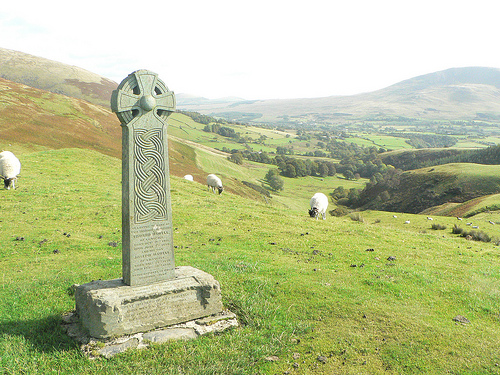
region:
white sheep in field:
[300, 197, 335, 231]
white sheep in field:
[205, 169, 230, 203]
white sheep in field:
[180, 166, 200, 187]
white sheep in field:
[0, 146, 27, 203]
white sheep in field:
[403, 216, 415, 231]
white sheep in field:
[389, 206, 396, 218]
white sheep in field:
[423, 214, 435, 222]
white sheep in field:
[457, 214, 465, 221]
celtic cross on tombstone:
[65, 63, 240, 354]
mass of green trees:
[283, 155, 346, 174]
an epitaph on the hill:
[86, 51, 243, 330]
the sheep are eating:
[209, 157, 353, 247]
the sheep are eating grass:
[207, 163, 364, 250]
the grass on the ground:
[205, 180, 357, 316]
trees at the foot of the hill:
[235, 134, 387, 227]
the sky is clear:
[180, 23, 344, 100]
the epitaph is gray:
[84, 57, 209, 274]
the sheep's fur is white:
[3, 144, 56, 226]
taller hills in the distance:
[285, 46, 497, 158]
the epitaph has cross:
[68, 82, 273, 334]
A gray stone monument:
[43, 65, 249, 361]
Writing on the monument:
[40, 62, 246, 359]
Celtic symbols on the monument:
[50, 50, 251, 365]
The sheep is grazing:
[301, 190, 332, 220]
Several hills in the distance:
[215, 55, 497, 185]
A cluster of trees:
[268, 151, 388, 182]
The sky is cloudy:
[8, 5, 498, 64]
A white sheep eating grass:
[202, 167, 228, 201]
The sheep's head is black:
[2, 150, 27, 194]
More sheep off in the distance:
[381, 205, 498, 244]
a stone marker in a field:
[64, 59, 253, 355]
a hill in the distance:
[394, 60, 497, 121]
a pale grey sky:
[1, 0, 496, 93]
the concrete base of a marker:
[78, 259, 233, 371]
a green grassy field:
[11, 150, 496, 369]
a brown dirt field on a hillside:
[5, 84, 218, 186]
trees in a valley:
[280, 154, 347, 181]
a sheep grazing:
[201, 167, 234, 196]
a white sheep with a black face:
[301, 188, 344, 232]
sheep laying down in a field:
[464, 219, 481, 231]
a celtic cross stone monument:
[80, 67, 237, 354]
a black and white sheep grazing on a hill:
[306, 191, 331, 221]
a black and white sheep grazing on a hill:
[204, 173, 224, 195]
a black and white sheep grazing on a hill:
[1, 148, 18, 195]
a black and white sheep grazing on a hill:
[392, 211, 401, 220]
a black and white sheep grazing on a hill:
[402, 216, 410, 223]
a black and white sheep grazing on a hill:
[425, 215, 433, 222]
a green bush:
[430, 220, 445, 230]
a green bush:
[451, 223, 462, 236]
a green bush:
[462, 230, 468, 237]